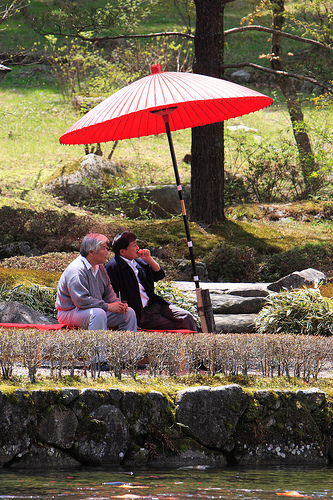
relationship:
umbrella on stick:
[59, 63, 272, 144] [160, 114, 215, 332]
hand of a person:
[140, 247, 156, 263] [49, 226, 140, 332]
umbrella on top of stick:
[59, 63, 273, 290] [153, 106, 211, 327]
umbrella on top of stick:
[59, 63, 272, 144] [162, 115, 200, 287]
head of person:
[76, 227, 111, 263] [54, 227, 131, 331]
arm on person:
[67, 280, 127, 315] [54, 227, 131, 331]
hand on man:
[138, 247, 152, 266] [107, 229, 199, 333]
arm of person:
[137, 247, 164, 278] [111, 227, 197, 331]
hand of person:
[138, 247, 152, 266] [99, 226, 211, 329]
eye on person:
[130, 243, 137, 247] [53, 232, 138, 329]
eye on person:
[101, 244, 106, 253] [111, 227, 197, 331]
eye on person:
[133, 243, 136, 247] [111, 227, 197, 331]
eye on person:
[98, 244, 105, 252] [53, 232, 138, 329]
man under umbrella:
[108, 233, 197, 329] [59, 63, 273, 290]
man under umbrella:
[55, 234, 137, 329] [59, 63, 273, 290]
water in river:
[226, 199, 319, 220] [2, 481, 321, 498]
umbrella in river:
[59, 63, 273, 290] [8, 469, 322, 498]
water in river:
[0, 471, 333, 498] [8, 469, 322, 498]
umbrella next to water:
[59, 63, 273, 290] [2, 458, 331, 498]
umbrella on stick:
[59, 63, 273, 290] [172, 150, 191, 269]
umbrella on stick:
[59, 63, 273, 290] [158, 108, 204, 296]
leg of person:
[162, 303, 198, 330] [111, 227, 197, 331]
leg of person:
[102, 304, 137, 331] [54, 227, 131, 331]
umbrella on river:
[59, 63, 273, 290] [1, 462, 329, 497]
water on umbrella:
[195, 280, 241, 289] [59, 63, 273, 290]